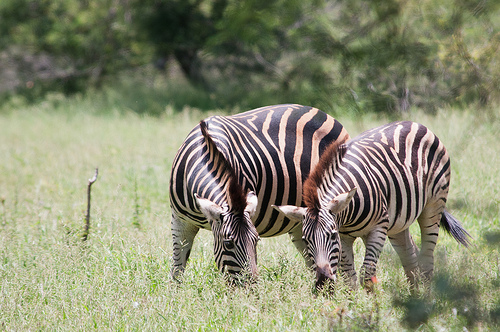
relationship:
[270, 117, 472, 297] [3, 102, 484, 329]
zebra grazing field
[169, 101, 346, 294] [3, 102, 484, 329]
zebra grazing field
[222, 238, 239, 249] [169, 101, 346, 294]
eye on zebra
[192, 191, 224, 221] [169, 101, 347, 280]
ear on zebra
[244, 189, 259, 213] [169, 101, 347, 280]
ear on zebra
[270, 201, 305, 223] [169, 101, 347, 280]
ear on zebra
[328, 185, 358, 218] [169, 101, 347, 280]
ear on zebra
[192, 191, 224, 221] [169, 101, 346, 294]
ear on zebra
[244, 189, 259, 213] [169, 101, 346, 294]
ear on zebra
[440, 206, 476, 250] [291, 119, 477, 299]
tail on zebra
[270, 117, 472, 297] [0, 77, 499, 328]
zebra eating grass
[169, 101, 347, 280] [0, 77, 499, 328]
zebra eating grass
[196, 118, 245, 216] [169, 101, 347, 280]
black mane on zebra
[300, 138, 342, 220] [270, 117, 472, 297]
black mane on zebra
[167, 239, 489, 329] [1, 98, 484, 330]
grass on ground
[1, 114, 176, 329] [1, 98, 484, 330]
grass on ground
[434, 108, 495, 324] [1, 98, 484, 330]
grass on ground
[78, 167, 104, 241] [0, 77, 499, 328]
stick standing up in grass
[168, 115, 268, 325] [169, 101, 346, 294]
black mane on zebra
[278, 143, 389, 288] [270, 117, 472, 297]
black mane on zebra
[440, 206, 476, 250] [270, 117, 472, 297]
tail on zebra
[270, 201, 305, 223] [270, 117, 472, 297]
ear on zebra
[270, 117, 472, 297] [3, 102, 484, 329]
zebra in field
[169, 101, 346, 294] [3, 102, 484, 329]
zebra in field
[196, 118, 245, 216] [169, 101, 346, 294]
black mane on zebra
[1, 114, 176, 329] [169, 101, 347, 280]
grass below zebra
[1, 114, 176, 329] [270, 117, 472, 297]
grass below zebra